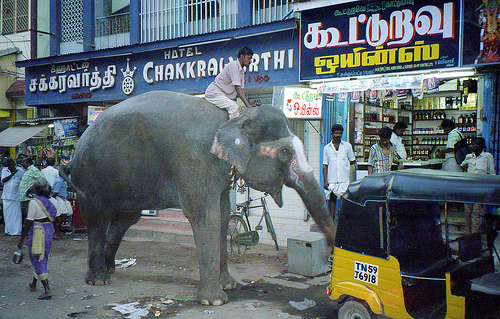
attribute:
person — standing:
[40, 155, 58, 188]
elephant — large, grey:
[60, 88, 327, 308]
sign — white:
[352, 260, 379, 287]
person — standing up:
[323, 120, 363, 220]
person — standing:
[320, 122, 352, 226]